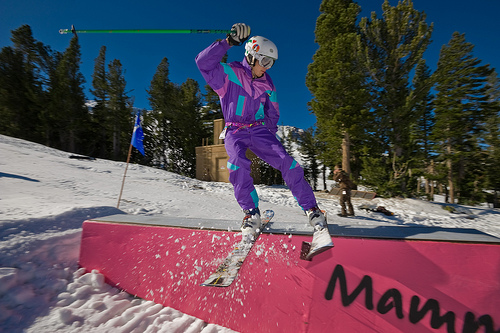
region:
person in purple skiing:
[173, 14, 343, 256]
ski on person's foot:
[305, 228, 347, 260]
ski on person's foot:
[195, 246, 279, 308]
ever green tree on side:
[379, 12, 432, 204]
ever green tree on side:
[431, 48, 485, 210]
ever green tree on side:
[303, 44, 368, 191]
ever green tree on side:
[99, 58, 132, 157]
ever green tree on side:
[52, 43, 87, 151]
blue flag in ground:
[121, 113, 156, 225]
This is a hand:
[180, 11, 240, 86]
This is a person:
[190, 16, 335, 252]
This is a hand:
[265, 78, 290, 139]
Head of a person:
[245, 32, 280, 79]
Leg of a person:
[220, 139, 264, 241]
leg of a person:
[252, 136, 347, 246]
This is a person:
[328, 153, 358, 217]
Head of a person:
[321, 152, 351, 176]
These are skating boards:
[204, 205, 336, 300]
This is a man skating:
[48, 16, 372, 313]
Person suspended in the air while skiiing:
[122, 12, 359, 262]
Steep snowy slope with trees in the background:
[17, 139, 137, 199]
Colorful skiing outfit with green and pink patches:
[210, 48, 288, 159]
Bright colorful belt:
[224, 110, 266, 130]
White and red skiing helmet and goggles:
[234, 29, 284, 76]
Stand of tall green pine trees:
[313, 0, 494, 160]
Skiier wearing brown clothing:
[324, 153, 372, 224]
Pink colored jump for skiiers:
[38, 200, 375, 331]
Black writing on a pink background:
[322, 252, 498, 331]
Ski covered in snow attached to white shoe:
[202, 200, 282, 280]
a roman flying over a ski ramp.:
[193, 20, 333, 286]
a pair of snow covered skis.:
[199, 214, 345, 299]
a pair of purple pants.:
[210, 120, 328, 214]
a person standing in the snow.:
[317, 160, 374, 217]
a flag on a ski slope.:
[107, 94, 162, 213]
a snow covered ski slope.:
[0, 130, 495, 332]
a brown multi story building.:
[189, 100, 284, 189]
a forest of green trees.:
[303, 5, 498, 191]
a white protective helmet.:
[235, 32, 305, 83]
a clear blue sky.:
[0, 0, 495, 153]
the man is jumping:
[35, 5, 389, 324]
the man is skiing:
[97, 16, 343, 296]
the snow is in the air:
[152, 216, 311, 317]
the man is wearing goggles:
[245, 47, 282, 76]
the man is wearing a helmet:
[235, 33, 282, 62]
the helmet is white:
[227, 30, 286, 60]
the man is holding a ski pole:
[36, 2, 246, 61]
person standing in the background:
[317, 137, 367, 221]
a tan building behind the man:
[176, 116, 266, 184]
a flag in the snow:
[95, 100, 161, 215]